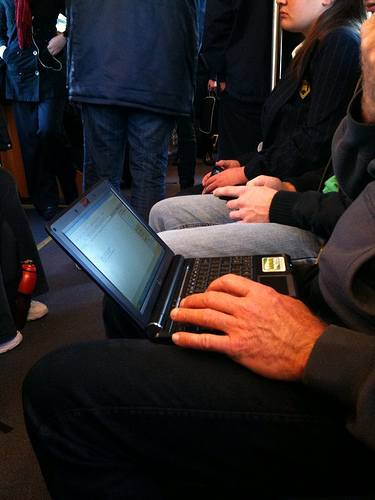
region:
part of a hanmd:
[255, 306, 290, 370]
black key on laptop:
[230, 257, 242, 264]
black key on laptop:
[240, 258, 251, 262]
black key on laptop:
[199, 257, 209, 264]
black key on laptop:
[199, 261, 207, 267]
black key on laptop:
[199, 265, 209, 268]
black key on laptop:
[193, 286, 205, 292]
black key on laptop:
[241, 267, 251, 276]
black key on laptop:
[242, 264, 251, 270]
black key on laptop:
[231, 263, 241, 269]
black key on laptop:
[185, 282, 192, 287]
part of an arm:
[246, 335, 256, 344]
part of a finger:
[201, 344, 202, 363]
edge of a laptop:
[163, 339, 169, 345]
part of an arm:
[228, 306, 248, 340]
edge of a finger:
[215, 323, 218, 334]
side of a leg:
[120, 420, 126, 433]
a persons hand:
[175, 275, 311, 381]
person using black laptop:
[46, 175, 300, 344]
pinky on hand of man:
[170, 331, 232, 355]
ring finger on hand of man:
[171, 306, 234, 332]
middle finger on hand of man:
[180, 291, 237, 312]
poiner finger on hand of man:
[203, 272, 250, 295]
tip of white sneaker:
[25, 300, 48, 318]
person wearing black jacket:
[68, 0, 207, 118]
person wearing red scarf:
[17, 2, 34, 49]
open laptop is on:
[44, 177, 302, 345]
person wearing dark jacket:
[244, 26, 362, 191]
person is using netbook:
[47, 176, 302, 344]